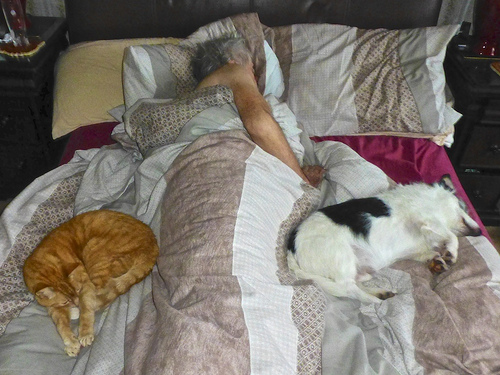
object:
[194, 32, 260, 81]
head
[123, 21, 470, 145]
pillow case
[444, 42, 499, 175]
end table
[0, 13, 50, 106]
nightstand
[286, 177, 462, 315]
cat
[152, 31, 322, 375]
man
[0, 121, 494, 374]
bed sheet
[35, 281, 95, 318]
head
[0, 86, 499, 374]
cover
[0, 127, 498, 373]
bed spread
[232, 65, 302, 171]
arm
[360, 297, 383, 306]
paw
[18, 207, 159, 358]
cat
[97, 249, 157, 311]
tail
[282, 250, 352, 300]
tail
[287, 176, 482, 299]
dog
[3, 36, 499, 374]
bed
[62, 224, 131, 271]
stripes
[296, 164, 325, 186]
hand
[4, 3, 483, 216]
tables